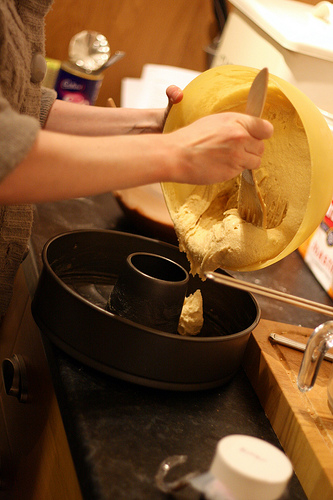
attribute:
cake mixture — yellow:
[175, 85, 312, 340]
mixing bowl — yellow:
[156, 61, 332, 275]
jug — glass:
[297, 315, 333, 418]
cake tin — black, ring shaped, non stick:
[27, 224, 265, 401]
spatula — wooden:
[236, 65, 272, 232]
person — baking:
[2, 0, 276, 323]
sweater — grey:
[1, 1, 59, 331]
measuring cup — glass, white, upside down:
[182, 431, 296, 499]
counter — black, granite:
[21, 135, 332, 499]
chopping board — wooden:
[234, 312, 333, 498]